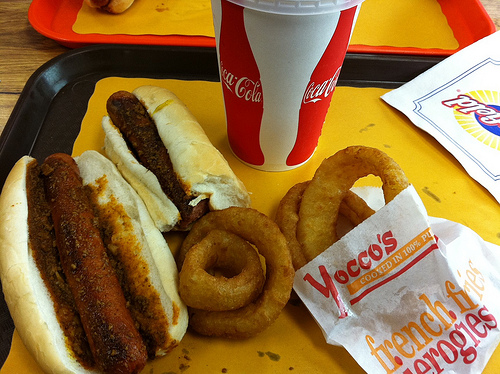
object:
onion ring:
[179, 229, 264, 312]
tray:
[0, 40, 499, 373]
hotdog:
[37, 153, 156, 374]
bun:
[74, 146, 193, 358]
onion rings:
[174, 205, 295, 339]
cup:
[208, 0, 364, 174]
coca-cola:
[216, 63, 262, 104]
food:
[0, 84, 412, 374]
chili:
[25, 189, 110, 294]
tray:
[27, 0, 492, 58]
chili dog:
[105, 91, 192, 223]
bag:
[288, 183, 498, 370]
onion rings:
[274, 144, 410, 273]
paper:
[290, 29, 499, 372]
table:
[0, 0, 60, 131]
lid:
[217, 0, 367, 19]